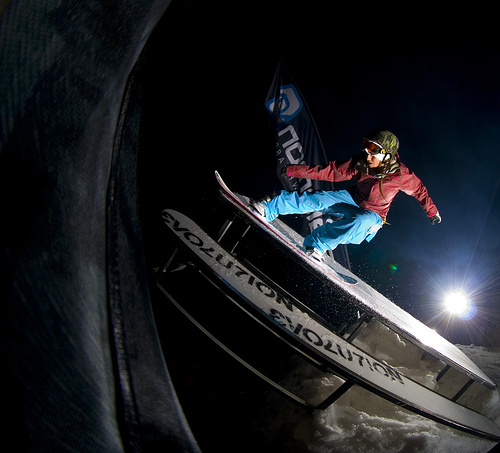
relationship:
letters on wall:
[278, 123, 338, 241] [147, 184, 496, 442]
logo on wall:
[266, 84, 303, 125] [133, 147, 496, 444]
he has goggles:
[247, 130, 442, 262] [357, 140, 396, 158]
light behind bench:
[421, 255, 488, 340] [156, 205, 498, 440]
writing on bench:
[163, 210, 405, 386] [152, 167, 498, 447]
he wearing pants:
[247, 130, 442, 262] [250, 188, 383, 265]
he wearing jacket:
[247, 130, 442, 262] [279, 145, 455, 223]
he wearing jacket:
[247, 130, 442, 262] [284, 153, 439, 222]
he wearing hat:
[247, 130, 442, 262] [364, 131, 400, 160]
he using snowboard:
[247, 130, 442, 262] [228, 177, 495, 390]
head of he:
[364, 136, 396, 172] [247, 130, 442, 262]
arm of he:
[398, 170, 446, 228] [247, 130, 442, 262]